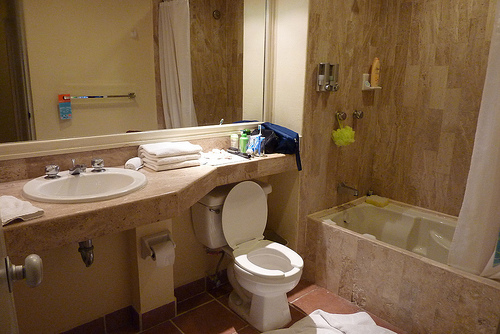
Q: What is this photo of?
A: A bathroom.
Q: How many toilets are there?
A: Just 1.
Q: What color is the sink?
A: White.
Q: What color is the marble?
A: Brown.